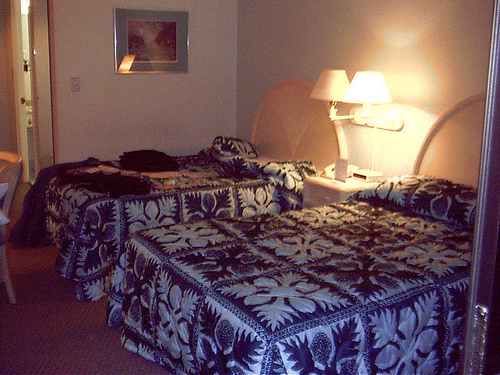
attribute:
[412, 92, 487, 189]
head board — blonde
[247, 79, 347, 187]
headboard — tan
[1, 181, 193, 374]
carpet — red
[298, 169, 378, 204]
table — white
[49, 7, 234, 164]
wall — tall, white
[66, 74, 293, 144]
wall — beige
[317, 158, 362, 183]
telephone — beige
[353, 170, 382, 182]
clock — white, radio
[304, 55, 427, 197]
light — beige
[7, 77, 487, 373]
beds — white, blue, double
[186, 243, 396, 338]
quilt — white, blue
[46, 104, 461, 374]
comforter — blue, white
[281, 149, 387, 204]
desk — small, brown, table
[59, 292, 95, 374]
carpet — brown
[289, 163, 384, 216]
table — brown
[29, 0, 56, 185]
mirror — tall, wall